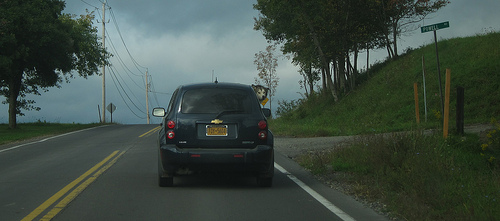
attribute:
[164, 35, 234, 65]
cloud — white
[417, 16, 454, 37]
sign — green street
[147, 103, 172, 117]
mirror — side 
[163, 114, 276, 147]
lights — Tail 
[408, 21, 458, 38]
sign — green street 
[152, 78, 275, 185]
car — dark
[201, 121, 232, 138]
license plate — yellow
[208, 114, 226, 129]
logo — Chevrolet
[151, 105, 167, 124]
mirror — rear view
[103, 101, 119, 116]
sign — diamond shaped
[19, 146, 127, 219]
line — double, yellow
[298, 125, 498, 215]
grass — green